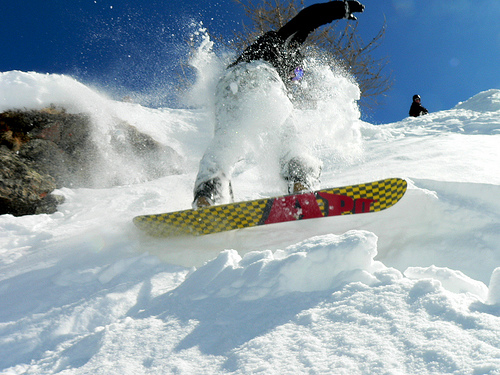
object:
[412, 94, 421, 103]
head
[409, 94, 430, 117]
man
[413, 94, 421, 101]
helmet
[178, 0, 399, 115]
tree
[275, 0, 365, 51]
arm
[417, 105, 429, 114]
arm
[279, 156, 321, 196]
boot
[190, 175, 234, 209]
boot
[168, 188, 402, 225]
underside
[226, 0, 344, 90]
coat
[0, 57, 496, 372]
snow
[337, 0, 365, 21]
hand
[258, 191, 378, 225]
letters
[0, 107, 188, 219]
rock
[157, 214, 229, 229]
pattern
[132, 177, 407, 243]
board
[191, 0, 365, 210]
man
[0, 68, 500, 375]
hill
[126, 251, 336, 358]
shadow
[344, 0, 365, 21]
glove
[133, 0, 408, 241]
skiing